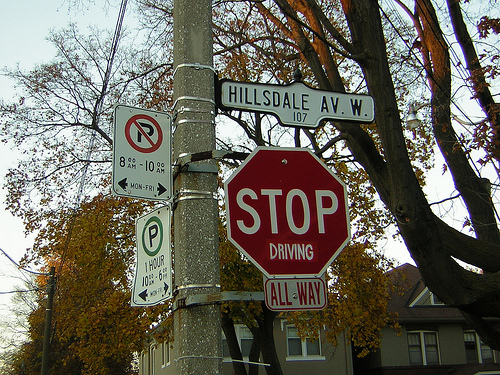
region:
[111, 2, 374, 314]
Street pole full of signs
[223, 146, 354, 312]
Red all-way stop sign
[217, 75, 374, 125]
"Hillsdale Av. W." street sign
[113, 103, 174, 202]
No-parking sign on pole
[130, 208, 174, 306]
1-hour parking sign on pole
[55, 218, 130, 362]
Bright yellow tree foliage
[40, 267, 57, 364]
Telephone pole in distance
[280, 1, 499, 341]
Branches of large tree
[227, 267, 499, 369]
Houses behind street pole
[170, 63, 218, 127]
Metal clamps holding signs on pole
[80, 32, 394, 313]
The pole has five signs.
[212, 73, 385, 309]
The address sign is above the stop sign.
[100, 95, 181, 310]
The parking sign is underneath the no parking sign.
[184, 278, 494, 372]
The houses are behind the sign.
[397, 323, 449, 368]
The window is closed.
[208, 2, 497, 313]
The tree is next to the signs.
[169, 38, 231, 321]
The signs are held up by metal clips.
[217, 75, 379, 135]
The sign has both letters and a number.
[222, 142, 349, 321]
The signs both have two words.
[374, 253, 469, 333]
The roof of the house is brown.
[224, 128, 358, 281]
a octagon plate on a stone pole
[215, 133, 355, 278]
a red plate with white frames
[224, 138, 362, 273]
a red stop sign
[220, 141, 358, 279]
a plate with white characters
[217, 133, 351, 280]
a plate with a stop sign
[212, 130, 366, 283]
a red plate of traffic sign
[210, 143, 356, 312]
a traffic stop sign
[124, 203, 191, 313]
a white plate mounted on a pole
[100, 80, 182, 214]
a no parking sign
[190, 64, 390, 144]
a street sign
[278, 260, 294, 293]
part of a board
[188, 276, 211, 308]
aprt of a oine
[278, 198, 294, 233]
part of a letter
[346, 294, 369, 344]
aprt of a tree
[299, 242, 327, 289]
part of a letter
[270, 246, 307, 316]
par tof a board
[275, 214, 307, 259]
part of a board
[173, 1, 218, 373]
pole with many signs on it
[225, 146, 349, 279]
octagonal sign is red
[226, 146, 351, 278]
stop sign is under street sign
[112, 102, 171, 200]
white no parking sign above white sign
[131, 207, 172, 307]
one hour parking sign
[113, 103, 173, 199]
white no parking sign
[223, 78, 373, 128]
white street sign with black edge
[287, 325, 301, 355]
glass window on tan house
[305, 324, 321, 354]
glass window on tan house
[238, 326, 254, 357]
glass window on tan house